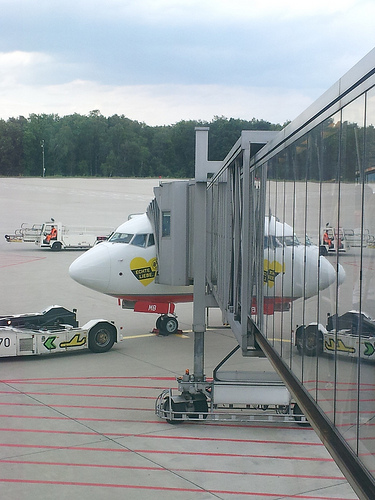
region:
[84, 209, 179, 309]
plane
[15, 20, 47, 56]
white clouds in blue sky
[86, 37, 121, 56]
white clouds in blue sky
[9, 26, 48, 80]
white clouds in blue sky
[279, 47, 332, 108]
white clouds in blue sky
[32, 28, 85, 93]
white clouds in blue sky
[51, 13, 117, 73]
white clouds in blue sky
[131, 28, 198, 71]
white clouds in blue sky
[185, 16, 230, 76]
white clouds in blue sky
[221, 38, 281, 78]
white clouds in blue sky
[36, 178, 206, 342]
a plane in an airport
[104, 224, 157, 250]
windows of the cockpit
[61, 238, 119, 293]
the nose of plane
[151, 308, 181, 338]
front wheel of plane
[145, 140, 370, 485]
loading bridge of plane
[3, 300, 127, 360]
a white car near the plane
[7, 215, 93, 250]
a man driving a truck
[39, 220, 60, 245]
man wears orange cloths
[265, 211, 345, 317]
reflection of plane on bridge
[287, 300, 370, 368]
reflection of car on bridge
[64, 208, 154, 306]
The nose of a plane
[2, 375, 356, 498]
Red lines on the tarmac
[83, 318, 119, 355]
A wheel is black and round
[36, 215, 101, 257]
A white vehicle on the tarmac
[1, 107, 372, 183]
Many green trees in the distance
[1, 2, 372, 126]
The sky appears to be overcast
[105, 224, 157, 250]
Windows on front of a plane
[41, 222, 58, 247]
A person is wearing orange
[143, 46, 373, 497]
A passageway leading to the plane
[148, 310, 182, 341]
Wheels under the airplane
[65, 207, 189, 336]
the plane is white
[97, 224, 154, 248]
the windows of a plane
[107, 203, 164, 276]
the cockpit of plane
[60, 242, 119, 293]
the nose of plane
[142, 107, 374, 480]
the bridge of plane is gray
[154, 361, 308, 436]
front wheels of bridge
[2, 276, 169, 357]
a truck near a plane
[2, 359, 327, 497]
red lines on ground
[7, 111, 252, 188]
green trees behind the airport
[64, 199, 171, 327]
front of a plane at an airport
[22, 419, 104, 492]
red painted lines on the ground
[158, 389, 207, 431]
wheels of a transporter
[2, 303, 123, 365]
car at an airport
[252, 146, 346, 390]
windows of an airport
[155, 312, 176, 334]
wheels of an airplane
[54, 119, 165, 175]
green trees in the background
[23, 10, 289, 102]
blue cloudy sky in the distance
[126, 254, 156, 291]
design on a plane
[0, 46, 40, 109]
white cloud in the sky